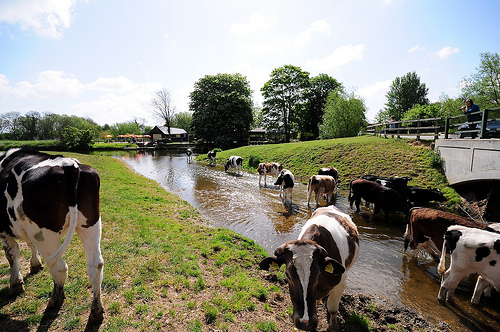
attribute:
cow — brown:
[272, 208, 365, 310]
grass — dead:
[110, 241, 256, 327]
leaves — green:
[184, 69, 254, 153]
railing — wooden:
[377, 105, 498, 142]